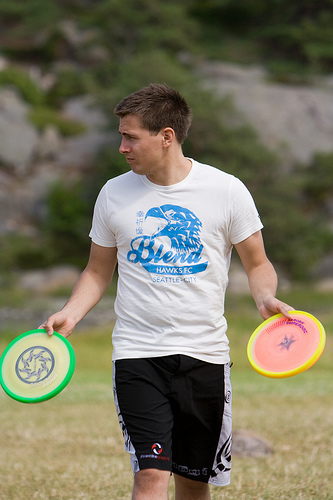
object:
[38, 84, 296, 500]
man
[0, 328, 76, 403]
frisbee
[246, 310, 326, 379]
frisbee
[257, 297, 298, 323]
hand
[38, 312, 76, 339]
hand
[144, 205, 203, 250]
hawk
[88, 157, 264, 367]
shirt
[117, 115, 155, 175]
face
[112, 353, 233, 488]
shorts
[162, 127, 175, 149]
ear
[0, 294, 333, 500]
grass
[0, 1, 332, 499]
park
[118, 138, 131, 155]
nose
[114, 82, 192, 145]
hair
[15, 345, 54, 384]
sun shape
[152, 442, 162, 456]
logo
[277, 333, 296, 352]
design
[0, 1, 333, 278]
foliage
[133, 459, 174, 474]
edge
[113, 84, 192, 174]
head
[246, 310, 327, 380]
trim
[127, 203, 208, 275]
design